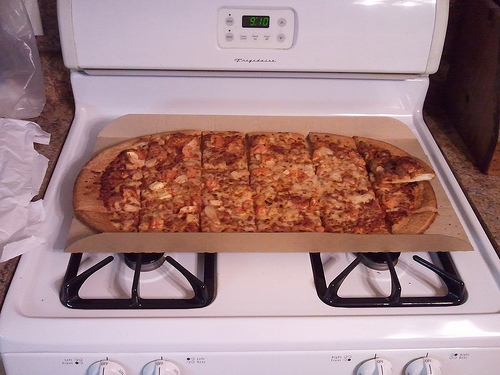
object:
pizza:
[200, 169, 257, 233]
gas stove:
[0, 0, 500, 375]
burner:
[308, 250, 470, 307]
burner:
[60, 252, 214, 310]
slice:
[201, 130, 248, 169]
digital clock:
[242, 15, 270, 28]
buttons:
[219, 7, 294, 49]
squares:
[137, 129, 256, 233]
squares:
[245, 131, 390, 235]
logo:
[234, 58, 277, 63]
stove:
[58, 252, 218, 309]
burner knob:
[404, 357, 440, 375]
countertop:
[422, 0, 500, 260]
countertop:
[0, 0, 75, 311]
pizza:
[352, 136, 435, 182]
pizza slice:
[140, 166, 204, 232]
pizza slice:
[249, 164, 326, 232]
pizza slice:
[316, 172, 392, 234]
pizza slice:
[369, 180, 438, 236]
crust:
[386, 145, 441, 240]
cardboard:
[64, 113, 474, 253]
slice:
[247, 131, 315, 173]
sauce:
[99, 131, 422, 233]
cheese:
[73, 130, 438, 234]